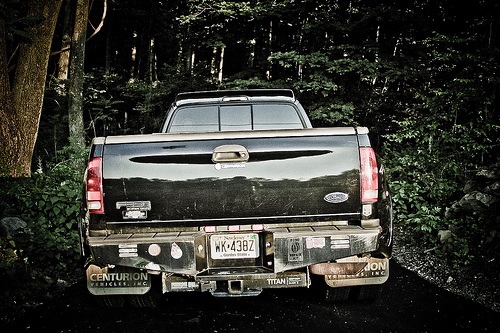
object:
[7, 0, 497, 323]
forest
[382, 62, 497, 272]
tree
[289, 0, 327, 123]
tree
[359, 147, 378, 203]
brake light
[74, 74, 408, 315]
ford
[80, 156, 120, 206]
brake light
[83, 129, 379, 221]
tailgate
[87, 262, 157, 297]
sticker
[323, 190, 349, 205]
logo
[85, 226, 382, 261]
bumper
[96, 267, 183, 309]
tire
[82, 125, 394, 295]
truck bed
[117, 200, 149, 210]
name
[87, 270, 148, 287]
centurion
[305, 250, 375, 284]
exhaust pipe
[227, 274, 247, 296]
trailer mount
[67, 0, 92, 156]
tree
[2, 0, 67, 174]
tree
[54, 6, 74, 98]
tree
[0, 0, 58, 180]
trunk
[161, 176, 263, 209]
reflection telephoto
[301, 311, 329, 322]
patch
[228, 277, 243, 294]
hitch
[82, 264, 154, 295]
tire flap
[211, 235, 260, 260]
license plate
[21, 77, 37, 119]
bark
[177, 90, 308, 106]
rack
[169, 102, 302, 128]
back window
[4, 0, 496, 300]
woods